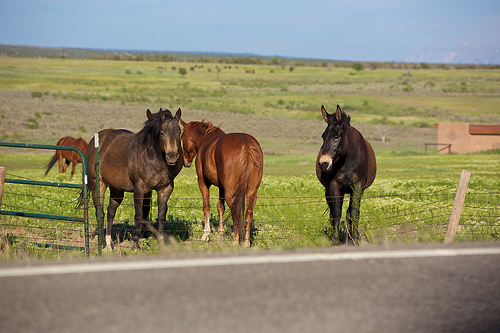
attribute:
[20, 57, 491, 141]
field — large